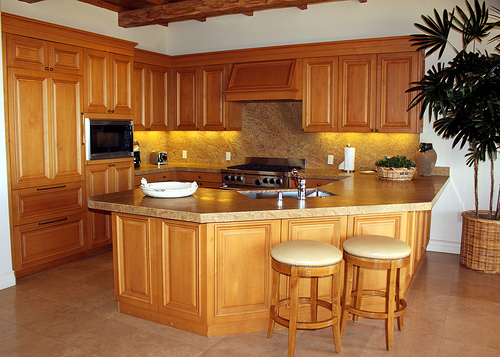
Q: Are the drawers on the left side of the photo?
A: Yes, the drawers are on the left of the image.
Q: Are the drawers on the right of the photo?
A: No, the drawers are on the left of the image.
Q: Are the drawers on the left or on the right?
A: The drawers are on the left of the image.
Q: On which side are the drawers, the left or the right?
A: The drawers are on the left of the image.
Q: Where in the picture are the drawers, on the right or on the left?
A: The drawers are on the left of the image.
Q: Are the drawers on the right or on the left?
A: The drawers are on the left of the image.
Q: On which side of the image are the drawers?
A: The drawers are on the left of the image.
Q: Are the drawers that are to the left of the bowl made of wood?
A: Yes, the drawers are made of wood.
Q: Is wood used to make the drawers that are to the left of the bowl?
A: Yes, the drawers are made of wood.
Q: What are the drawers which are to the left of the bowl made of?
A: The drawers are made of wood.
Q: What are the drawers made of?
A: The drawers are made of wood.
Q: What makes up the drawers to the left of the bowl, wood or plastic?
A: The drawers are made of wood.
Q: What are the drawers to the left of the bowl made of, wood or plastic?
A: The drawers are made of wood.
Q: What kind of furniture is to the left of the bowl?
A: The pieces of furniture are drawers.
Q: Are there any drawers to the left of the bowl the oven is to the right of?
A: Yes, there are drawers to the left of the bowl.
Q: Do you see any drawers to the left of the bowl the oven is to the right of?
A: Yes, there are drawers to the left of the bowl.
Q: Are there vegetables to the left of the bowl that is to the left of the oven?
A: No, there are drawers to the left of the bowl.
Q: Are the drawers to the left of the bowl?
A: Yes, the drawers are to the left of the bowl.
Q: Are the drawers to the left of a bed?
A: No, the drawers are to the left of the bowl.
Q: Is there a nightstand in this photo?
A: No, there are no nightstands.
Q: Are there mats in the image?
A: No, there are no mats.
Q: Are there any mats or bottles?
A: No, there are no mats or bottles.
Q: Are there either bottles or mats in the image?
A: No, there are no mats or bottles.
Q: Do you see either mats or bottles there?
A: No, there are no mats or bottles.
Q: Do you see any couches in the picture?
A: No, there are no couches.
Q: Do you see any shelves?
A: No, there are no shelves.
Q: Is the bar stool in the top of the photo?
A: No, the bar stool is in the bottom of the image.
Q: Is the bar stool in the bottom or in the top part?
A: The bar stool is in the bottom of the image.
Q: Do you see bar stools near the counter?
A: Yes, there is a bar stool near the counter.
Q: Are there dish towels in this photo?
A: No, there are no dish towels.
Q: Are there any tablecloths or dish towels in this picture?
A: No, there are no dish towels or tablecloths.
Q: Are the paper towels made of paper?
A: Yes, the paper towels are made of paper.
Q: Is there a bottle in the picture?
A: No, there are no bottles.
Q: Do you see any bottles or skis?
A: No, there are no bottles or skis.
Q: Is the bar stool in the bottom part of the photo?
A: Yes, the bar stool is in the bottom of the image.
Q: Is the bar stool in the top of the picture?
A: No, the bar stool is in the bottom of the image.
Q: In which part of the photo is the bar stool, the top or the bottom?
A: The bar stool is in the bottom of the image.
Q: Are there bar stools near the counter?
A: Yes, there is a bar stool near the counter.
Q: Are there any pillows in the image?
A: No, there are no pillows.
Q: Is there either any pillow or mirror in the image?
A: No, there are no pillows or mirrors.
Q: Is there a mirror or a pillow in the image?
A: No, there are no pillows or mirrors.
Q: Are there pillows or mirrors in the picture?
A: No, there are no pillows or mirrors.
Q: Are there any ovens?
A: Yes, there is an oven.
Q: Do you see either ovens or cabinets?
A: Yes, there is an oven.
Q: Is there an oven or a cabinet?
A: Yes, there is an oven.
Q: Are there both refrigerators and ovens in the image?
A: No, there is an oven but no refrigerators.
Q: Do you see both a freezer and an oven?
A: No, there is an oven but no refrigerators.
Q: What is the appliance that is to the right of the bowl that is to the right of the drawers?
A: The appliance is an oven.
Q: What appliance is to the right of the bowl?
A: The appliance is an oven.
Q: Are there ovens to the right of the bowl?
A: Yes, there is an oven to the right of the bowl.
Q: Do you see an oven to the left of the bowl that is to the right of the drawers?
A: No, the oven is to the right of the bowl.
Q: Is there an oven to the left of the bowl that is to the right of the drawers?
A: No, the oven is to the right of the bowl.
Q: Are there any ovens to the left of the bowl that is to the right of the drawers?
A: No, the oven is to the right of the bowl.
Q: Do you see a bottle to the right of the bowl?
A: No, there is an oven to the right of the bowl.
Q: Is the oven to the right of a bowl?
A: Yes, the oven is to the right of a bowl.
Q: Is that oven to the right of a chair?
A: No, the oven is to the right of a bowl.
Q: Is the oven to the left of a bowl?
A: No, the oven is to the right of a bowl.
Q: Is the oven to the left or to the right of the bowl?
A: The oven is to the right of the bowl.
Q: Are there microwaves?
A: Yes, there is a microwave.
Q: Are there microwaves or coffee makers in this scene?
A: Yes, there is a microwave.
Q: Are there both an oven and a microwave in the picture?
A: Yes, there are both a microwave and an oven.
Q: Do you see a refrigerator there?
A: No, there are no refrigerators.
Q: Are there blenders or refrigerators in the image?
A: No, there are no refrigerators or blenders.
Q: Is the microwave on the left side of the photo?
A: Yes, the microwave is on the left of the image.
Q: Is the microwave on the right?
A: No, the microwave is on the left of the image.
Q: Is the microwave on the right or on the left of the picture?
A: The microwave is on the left of the image.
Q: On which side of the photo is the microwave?
A: The microwave is on the left of the image.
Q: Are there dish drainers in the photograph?
A: No, there are no dish drainers.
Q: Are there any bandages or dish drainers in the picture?
A: No, there are no dish drainers or bandages.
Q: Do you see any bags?
A: No, there are no bags.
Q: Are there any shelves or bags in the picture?
A: No, there are no bags or shelves.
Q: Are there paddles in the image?
A: No, there are no paddles.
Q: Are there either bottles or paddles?
A: No, there are no paddles or bottles.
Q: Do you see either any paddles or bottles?
A: No, there are no paddles or bottles.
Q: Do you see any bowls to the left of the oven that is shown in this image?
A: Yes, there is a bowl to the left of the oven.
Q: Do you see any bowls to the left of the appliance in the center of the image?
A: Yes, there is a bowl to the left of the oven.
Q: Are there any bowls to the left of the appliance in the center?
A: Yes, there is a bowl to the left of the oven.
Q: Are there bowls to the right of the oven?
A: No, the bowl is to the left of the oven.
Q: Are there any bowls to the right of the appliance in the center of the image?
A: No, the bowl is to the left of the oven.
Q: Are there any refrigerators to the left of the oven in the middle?
A: No, there is a bowl to the left of the oven.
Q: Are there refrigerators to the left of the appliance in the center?
A: No, there is a bowl to the left of the oven.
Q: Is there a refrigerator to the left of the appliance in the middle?
A: No, there is a bowl to the left of the oven.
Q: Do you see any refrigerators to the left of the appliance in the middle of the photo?
A: No, there is a bowl to the left of the oven.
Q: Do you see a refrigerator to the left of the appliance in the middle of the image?
A: No, there is a bowl to the left of the oven.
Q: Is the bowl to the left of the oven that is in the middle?
A: Yes, the bowl is to the left of the oven.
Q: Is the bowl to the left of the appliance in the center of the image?
A: Yes, the bowl is to the left of the oven.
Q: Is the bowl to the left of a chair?
A: No, the bowl is to the left of the oven.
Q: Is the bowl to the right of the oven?
A: No, the bowl is to the left of the oven.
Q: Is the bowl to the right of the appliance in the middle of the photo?
A: No, the bowl is to the left of the oven.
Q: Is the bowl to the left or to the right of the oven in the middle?
A: The bowl is to the left of the oven.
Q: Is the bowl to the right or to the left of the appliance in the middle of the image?
A: The bowl is to the left of the oven.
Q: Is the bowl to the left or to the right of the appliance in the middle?
A: The bowl is to the left of the oven.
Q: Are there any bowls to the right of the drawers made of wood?
A: Yes, there is a bowl to the right of the drawers.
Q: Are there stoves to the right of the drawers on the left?
A: No, there is a bowl to the right of the drawers.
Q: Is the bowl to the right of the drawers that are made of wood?
A: Yes, the bowl is to the right of the drawers.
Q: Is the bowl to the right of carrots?
A: No, the bowl is to the right of the drawers.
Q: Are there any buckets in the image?
A: No, there are no buckets.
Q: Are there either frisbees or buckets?
A: No, there are no buckets or frisbees.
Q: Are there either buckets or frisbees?
A: No, there are no buckets or frisbees.